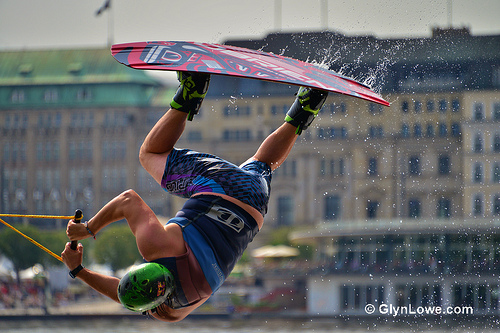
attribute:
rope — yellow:
[1, 214, 84, 265]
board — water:
[97, 35, 407, 111]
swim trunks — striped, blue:
[153, 140, 281, 215]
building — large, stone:
[2, 36, 147, 200]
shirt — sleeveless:
[154, 189, 263, 306]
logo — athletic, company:
[205, 204, 245, 232]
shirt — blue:
[143, 194, 259, 307]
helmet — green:
[116, 260, 176, 312]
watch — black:
[65, 264, 82, 279]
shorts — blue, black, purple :
[154, 140, 273, 215]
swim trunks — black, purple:
[162, 146, 270, 216]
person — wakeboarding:
[11, 3, 434, 330]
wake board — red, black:
[109, 40, 390, 108]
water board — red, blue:
[111, 37, 392, 106]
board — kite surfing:
[106, 39, 398, 109]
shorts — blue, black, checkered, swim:
[161, 146, 272, 214]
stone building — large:
[1, 25, 498, 225]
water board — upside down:
[45, 22, 417, 134]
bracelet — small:
[65, 214, 106, 238]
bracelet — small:
[29, 50, 394, 329]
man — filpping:
[37, 59, 427, 308]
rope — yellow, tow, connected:
[0, 210, 85, 282]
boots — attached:
[173, 71, 325, 135]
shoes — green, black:
[152, 59, 341, 144]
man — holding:
[72, 140, 305, 318]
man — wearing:
[94, 137, 306, 262]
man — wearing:
[49, 69, 328, 332]